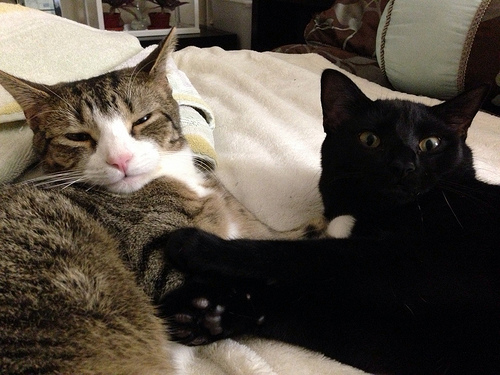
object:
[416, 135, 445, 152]
eye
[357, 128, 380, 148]
eye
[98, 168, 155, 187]
mouth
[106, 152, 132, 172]
nose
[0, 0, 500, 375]
duvet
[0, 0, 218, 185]
blanket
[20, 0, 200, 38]
bookshelf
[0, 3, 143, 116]
pillow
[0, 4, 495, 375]
bed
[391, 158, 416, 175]
nose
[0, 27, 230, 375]
cat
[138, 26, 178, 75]
right ear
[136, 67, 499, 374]
black cat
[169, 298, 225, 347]
paws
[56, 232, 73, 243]
grey fur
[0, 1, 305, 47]
background